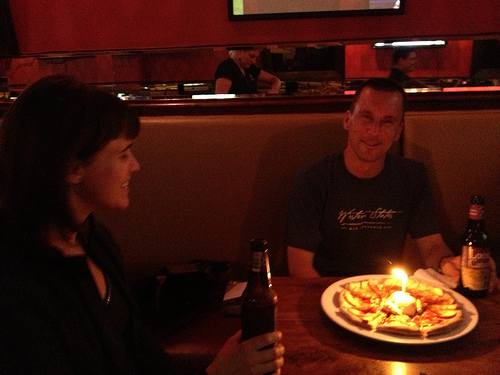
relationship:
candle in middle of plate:
[402, 280, 405, 298] [320, 273, 480, 345]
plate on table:
[320, 273, 480, 345] [164, 275, 498, 374]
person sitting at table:
[285, 77, 496, 295] [164, 275, 498, 374]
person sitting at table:
[0, 73, 286, 374] [164, 275, 498, 374]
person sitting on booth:
[285, 77, 496, 295] [89, 91, 499, 274]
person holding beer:
[285, 77, 496, 295] [459, 193, 490, 298]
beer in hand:
[459, 193, 490, 298] [439, 252, 498, 295]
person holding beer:
[0, 73, 286, 374] [239, 236, 279, 374]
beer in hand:
[239, 236, 279, 374] [205, 328, 285, 374]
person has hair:
[0, 73, 286, 374] [1, 72, 141, 264]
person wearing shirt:
[0, 73, 286, 374] [0, 215, 211, 374]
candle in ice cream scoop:
[402, 280, 405, 298] [387, 290, 416, 306]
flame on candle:
[390, 266, 410, 284] [402, 280, 405, 298]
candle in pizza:
[402, 280, 405, 298] [339, 278, 463, 336]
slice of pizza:
[377, 312, 421, 337] [339, 278, 463, 336]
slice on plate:
[377, 312, 421, 337] [320, 273, 480, 345]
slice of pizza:
[411, 308, 463, 338] [339, 278, 463, 336]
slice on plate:
[411, 308, 463, 338] [320, 273, 480, 345]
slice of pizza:
[340, 306, 390, 331] [339, 278, 463, 336]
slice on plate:
[340, 306, 390, 331] [320, 273, 480, 345]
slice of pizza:
[336, 289, 380, 311] [339, 278, 463, 336]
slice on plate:
[336, 289, 380, 311] [320, 273, 480, 345]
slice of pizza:
[343, 277, 386, 304] [339, 278, 463, 336]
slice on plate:
[343, 277, 386, 304] [320, 273, 480, 345]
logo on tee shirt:
[336, 207, 403, 225] [285, 149, 442, 276]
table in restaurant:
[164, 275, 498, 374] [0, 1, 499, 374]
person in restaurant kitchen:
[214, 47, 282, 96] [0, 39, 499, 102]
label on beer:
[461, 245, 490, 291] [459, 193, 490, 298]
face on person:
[115, 142, 142, 211] [0, 73, 286, 374]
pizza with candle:
[339, 278, 463, 336] [402, 280, 405, 298]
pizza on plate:
[339, 278, 463, 336] [320, 273, 480, 345]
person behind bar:
[214, 47, 282, 96] [1, 90, 500, 120]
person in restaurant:
[285, 77, 496, 295] [0, 1, 499, 374]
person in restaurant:
[0, 73, 286, 374] [0, 1, 499, 374]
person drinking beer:
[285, 77, 496, 295] [459, 193, 490, 298]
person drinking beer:
[0, 73, 286, 374] [239, 236, 279, 374]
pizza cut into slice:
[339, 278, 463, 336] [343, 277, 386, 304]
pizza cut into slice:
[339, 278, 463, 336] [336, 289, 380, 311]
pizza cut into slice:
[339, 278, 463, 336] [340, 306, 390, 331]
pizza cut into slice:
[339, 278, 463, 336] [377, 312, 421, 337]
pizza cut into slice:
[339, 278, 463, 336] [411, 308, 463, 338]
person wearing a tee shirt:
[285, 77, 496, 295] [285, 149, 442, 276]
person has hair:
[285, 77, 496, 295] [349, 76, 405, 124]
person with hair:
[0, 73, 286, 374] [1, 72, 141, 264]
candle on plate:
[402, 280, 405, 298] [320, 273, 480, 345]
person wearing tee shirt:
[285, 77, 496, 295] [285, 149, 442, 276]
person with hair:
[214, 47, 282, 96] [228, 47, 264, 59]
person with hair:
[285, 77, 496, 295] [349, 76, 405, 124]